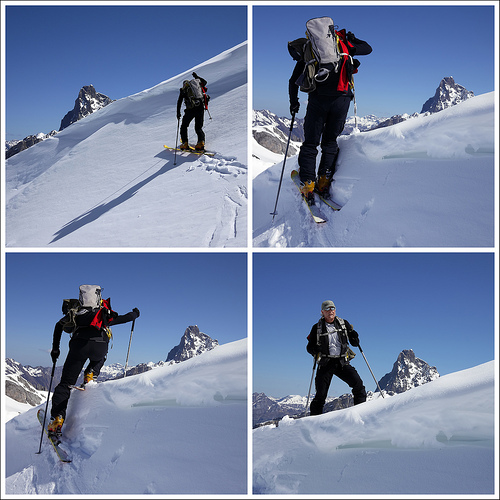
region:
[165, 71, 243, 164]
skier on side of mountain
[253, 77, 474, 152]
mountains under snow patches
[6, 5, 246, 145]
blue of daytime sky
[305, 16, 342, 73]
backpack on man's back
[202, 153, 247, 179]
ski marks in snow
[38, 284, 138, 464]
skier stepping up on incline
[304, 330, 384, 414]
two poles in skiers hands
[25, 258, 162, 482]
a man on skis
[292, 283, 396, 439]
man holding ski poles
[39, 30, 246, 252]
man walking at an angle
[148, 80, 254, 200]
tracks in the snow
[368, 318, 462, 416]
mountain peak in background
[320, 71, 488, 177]
a ledge of snow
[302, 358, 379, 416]
man wearing black pants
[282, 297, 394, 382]
man wearing a black jacket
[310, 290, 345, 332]
man wearing a hat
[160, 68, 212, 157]
a snow skier on mountain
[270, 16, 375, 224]
a snow skier on mountain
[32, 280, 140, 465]
a snow skier on mountain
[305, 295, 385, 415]
a snow skier on mountain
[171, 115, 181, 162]
a black snow pole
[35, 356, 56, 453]
a black snow pole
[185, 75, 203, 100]
a grey back pack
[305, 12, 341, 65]
a grey back pack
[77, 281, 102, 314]
a grey back pack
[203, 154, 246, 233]
tracks in the snow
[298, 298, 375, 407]
man wearing gray hat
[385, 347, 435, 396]
mountain in the distance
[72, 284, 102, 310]
gray backpack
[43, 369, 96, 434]
yellow ski boots man is wearing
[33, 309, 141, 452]
black and white ski poles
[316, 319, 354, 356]
straps of the backpack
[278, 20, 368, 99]
black and red jacket man is wearing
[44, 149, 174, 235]
shadow of the skier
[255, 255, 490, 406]
sky behind the skier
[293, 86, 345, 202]
the pants are black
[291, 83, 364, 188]
the pants are black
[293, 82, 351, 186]
the pants are black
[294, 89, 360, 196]
the pants are black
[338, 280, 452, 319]
the sky is clear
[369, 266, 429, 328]
the sky is clear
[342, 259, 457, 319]
the sky is clear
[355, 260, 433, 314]
the sky is clear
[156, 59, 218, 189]
man is walking on the snow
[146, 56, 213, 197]
man is walking on the snow